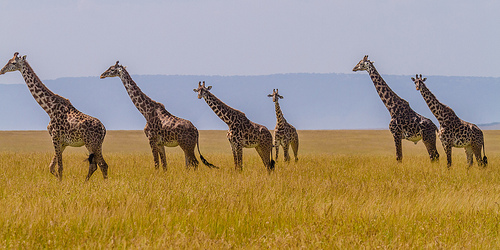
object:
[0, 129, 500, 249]
grass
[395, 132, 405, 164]
legs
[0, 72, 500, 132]
hills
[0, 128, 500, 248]
field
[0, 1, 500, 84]
sky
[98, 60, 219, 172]
giraffe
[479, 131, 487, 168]
tail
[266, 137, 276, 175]
tail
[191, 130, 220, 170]
tail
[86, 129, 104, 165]
tail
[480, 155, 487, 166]
tip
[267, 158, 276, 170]
tip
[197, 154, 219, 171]
tip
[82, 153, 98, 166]
tip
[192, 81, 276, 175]
giraffe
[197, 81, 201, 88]
horns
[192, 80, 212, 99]
head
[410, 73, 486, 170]
giraffe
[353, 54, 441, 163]
giraffe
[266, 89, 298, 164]
giraffe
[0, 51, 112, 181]
giraffe